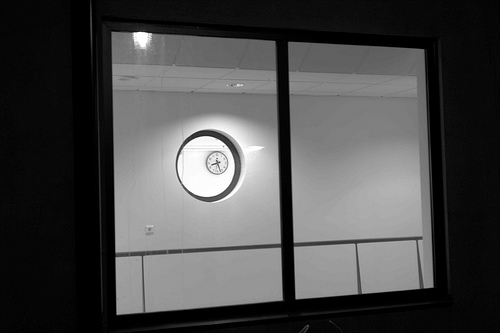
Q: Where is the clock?
A: On the wall.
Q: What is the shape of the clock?
A: Circle.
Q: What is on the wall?
A: A clock.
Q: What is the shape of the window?
A: Rectangle.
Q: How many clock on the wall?
A: One.